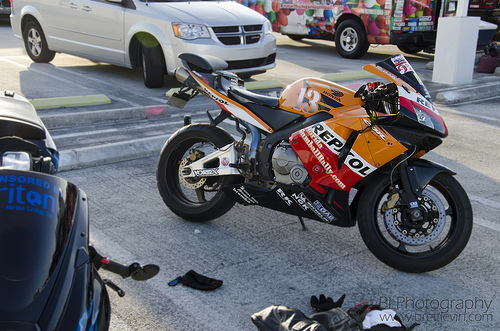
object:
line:
[4, 52, 176, 126]